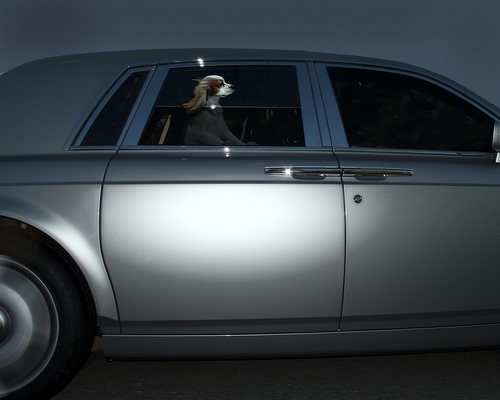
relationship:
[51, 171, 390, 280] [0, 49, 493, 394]
light in chrome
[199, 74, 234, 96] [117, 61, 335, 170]
head partially out of window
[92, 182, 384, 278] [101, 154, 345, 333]
light hitting door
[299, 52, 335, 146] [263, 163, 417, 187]
line over handles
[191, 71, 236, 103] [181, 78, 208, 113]
head with hair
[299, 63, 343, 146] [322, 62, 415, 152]
panel behind window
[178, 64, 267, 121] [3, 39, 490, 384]
dog looking from car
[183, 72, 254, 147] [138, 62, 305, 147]
dog head out of window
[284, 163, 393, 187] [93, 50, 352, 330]
handle of door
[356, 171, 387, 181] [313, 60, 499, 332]
handle of door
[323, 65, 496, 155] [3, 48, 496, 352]
tinted window of grey car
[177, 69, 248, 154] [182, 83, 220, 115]
dog with ears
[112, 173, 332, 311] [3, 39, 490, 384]
reflection on car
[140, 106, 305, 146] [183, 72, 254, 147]
window rolled down for dog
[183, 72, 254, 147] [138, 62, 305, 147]
dog in window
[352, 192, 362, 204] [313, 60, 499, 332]
key opening on door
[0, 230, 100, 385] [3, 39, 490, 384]
wheel of car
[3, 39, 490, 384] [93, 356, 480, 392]
car on road